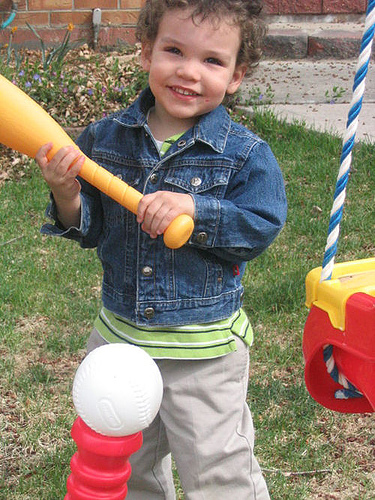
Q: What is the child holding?
A: A bat.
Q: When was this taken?
A: Daytime.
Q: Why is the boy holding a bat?
A: To hit the ball.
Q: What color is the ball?
A: White.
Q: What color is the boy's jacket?
A: Blue.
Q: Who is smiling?
A: The boy.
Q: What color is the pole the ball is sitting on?
A: Red.